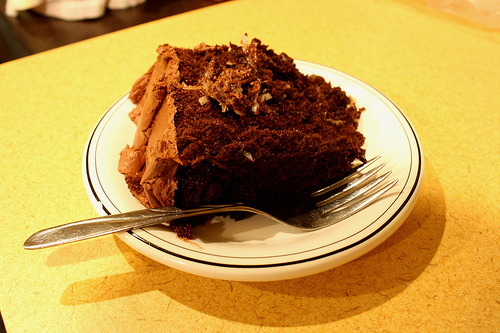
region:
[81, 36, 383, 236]
Food is in the foreground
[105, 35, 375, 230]
A brown chocolate cake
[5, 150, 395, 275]
A fork is in the foreground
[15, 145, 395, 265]
The fork is silver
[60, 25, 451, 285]
Cake is on a plate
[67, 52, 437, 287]
The plate is white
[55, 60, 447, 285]
A black ring is around the edge of plate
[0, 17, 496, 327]
Table is tan colored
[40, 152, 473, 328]
Plate and fork are casting a shadow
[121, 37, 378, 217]
Cake is brown in color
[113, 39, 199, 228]
Light brown frosting on the cake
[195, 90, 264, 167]
White pieces inside the cake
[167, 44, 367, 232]
Dark brown filling of the cake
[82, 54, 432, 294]
White and blue plate cake is sitting on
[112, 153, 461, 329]
Shadow on table of white plate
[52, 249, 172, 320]
Shadow on table of fork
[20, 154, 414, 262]
Silver fork sitting next to cake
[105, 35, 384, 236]
Slice of cake sitting on plate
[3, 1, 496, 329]
Yellowish table plate is sitting on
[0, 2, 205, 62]
Brown wooden table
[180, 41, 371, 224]
chocolate cake on plate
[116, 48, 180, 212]
chocolate frosting on cake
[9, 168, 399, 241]
silver metal dinner fork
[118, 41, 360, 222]
slice of chocolate cake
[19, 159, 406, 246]
metal fork on plate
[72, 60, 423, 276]
white ceramic dessert plate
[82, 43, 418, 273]
plate of cake on table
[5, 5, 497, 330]
light tan dinner table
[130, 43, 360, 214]
dessert on white plate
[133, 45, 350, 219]
chocolate cake on dessert plate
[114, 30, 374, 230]
a piece of chocolate cake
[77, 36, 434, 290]
a piece of chocolate cake on a dish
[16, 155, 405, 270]
a fork color silver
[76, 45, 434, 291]
a white dish on a yellow table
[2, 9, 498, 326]
a yellow table under a dish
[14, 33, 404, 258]
a silver fork next a cake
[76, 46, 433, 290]
border of dish has blue line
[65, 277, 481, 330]
shadow on yellow table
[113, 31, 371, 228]
a triangular piece of cake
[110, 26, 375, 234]
cake has chocolate frosting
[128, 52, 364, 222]
The cake has brown frosting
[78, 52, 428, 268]
The plate is round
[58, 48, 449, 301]
The plate is on the counter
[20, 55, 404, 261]
A fork next to the cake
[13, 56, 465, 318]
The counter is yellow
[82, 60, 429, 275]
The plate has a black stripe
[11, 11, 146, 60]
The floor is dark brown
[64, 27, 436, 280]
the cake is in a bowl